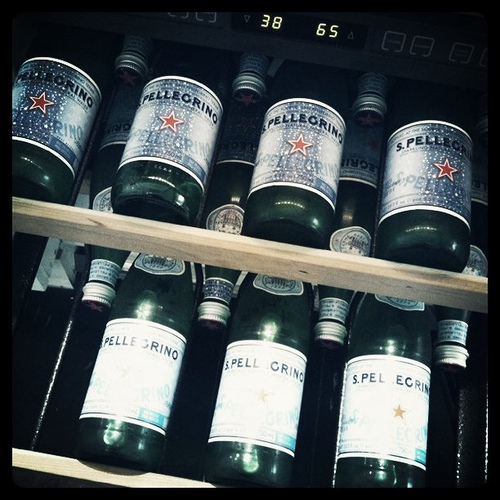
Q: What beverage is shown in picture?
A: Beer in a cooler.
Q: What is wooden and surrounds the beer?
A: A shelf holding the bottles.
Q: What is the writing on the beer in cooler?
A: The label on the bottle.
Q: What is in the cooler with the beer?
A: A bottle of wine.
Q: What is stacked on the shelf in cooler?
A: A bottle of wine.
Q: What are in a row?
A: Bottles.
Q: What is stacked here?
A: Wine bottles.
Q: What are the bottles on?
A: Shelves.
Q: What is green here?
A: The bottles.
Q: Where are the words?
A: On the labels.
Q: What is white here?
A: The labels.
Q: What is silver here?
A: The labels.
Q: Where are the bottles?
A: On racks.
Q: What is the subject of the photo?
A: Bottles.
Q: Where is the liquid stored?
A: In green bottles.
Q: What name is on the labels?
A: S. Pellegrino.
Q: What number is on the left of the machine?
A: 38.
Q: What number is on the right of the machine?
A: 65.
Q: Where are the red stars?
A: On bottles.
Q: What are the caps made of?
A: Metal.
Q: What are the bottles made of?
A: Glass.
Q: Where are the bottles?
A: On a rack.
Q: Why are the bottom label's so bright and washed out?
A: Light.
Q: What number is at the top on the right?
A: 65.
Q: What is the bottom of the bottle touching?
A: Wood.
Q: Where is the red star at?
A: On the label.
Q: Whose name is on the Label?
A: S. Pellegrino.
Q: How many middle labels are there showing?
A: 11.